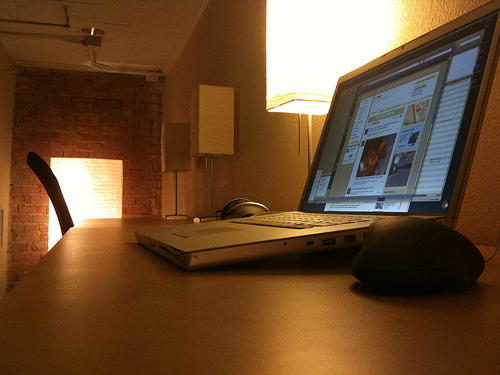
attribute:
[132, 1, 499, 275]
laptop — powered, matte silver, open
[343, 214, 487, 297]
mouse — black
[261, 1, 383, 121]
light — powered, lit up, on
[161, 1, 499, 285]
wall — brick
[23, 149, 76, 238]
chair — black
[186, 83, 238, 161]
light — not on, off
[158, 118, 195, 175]
shade — white, square, rectangular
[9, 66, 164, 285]
wall — brick, red